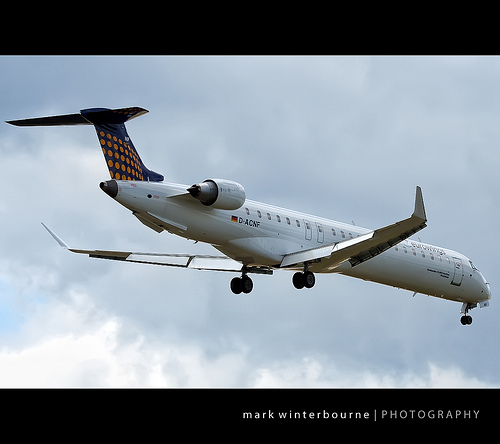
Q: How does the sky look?
A: Cloudy.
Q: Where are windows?
A: On side of plane.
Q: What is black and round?
A: Wheels.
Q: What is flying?
A: An airplane.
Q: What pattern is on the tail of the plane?
A: Orange dots.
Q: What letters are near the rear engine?
A: D-ACNF.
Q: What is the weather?
A: Cloudy.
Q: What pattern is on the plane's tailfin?
A: Polka dots.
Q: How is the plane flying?
A: With its engines.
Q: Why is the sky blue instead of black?
A: The sun is out.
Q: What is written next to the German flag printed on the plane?
A: D-ACNF.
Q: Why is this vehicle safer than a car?
A: There are fewer planes in the air than cars on the road.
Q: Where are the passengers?
A: Behind the windows.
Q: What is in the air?
A: White plane.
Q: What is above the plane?
A: Clouds.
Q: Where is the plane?
A: In the air.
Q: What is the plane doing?
A: Flying.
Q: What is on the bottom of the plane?
A: Landing gear.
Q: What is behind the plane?
A: Tail.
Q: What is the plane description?
A: Blue and orange.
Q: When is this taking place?
A: Daytime.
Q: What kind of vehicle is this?
A: Airplane.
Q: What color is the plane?
A: White, red, and blue.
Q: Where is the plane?
A: Sky.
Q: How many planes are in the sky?
A: One.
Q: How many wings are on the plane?
A: Two.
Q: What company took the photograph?
A: Mark winterbourne photography.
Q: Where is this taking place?
A: In the air.